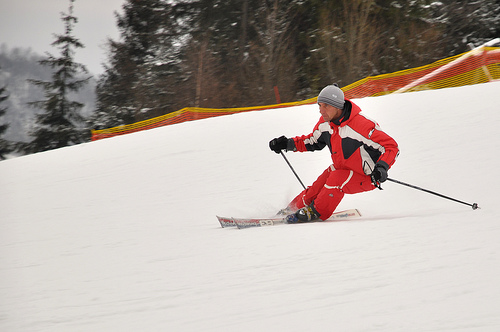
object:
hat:
[317, 82, 346, 109]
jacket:
[289, 97, 401, 178]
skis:
[386, 176, 482, 210]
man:
[268, 82, 400, 224]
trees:
[164, 27, 242, 120]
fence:
[90, 46, 500, 141]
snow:
[0, 79, 500, 332]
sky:
[0, 0, 208, 80]